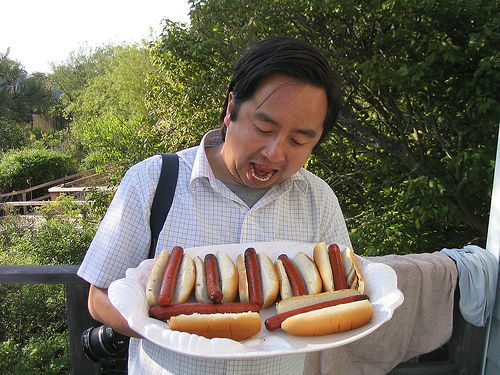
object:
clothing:
[441, 244, 500, 328]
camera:
[76, 325, 132, 363]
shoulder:
[141, 144, 202, 208]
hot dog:
[148, 301, 261, 319]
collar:
[188, 126, 308, 204]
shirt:
[75, 126, 356, 375]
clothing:
[306, 250, 460, 375]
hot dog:
[264, 292, 372, 332]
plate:
[106, 240, 405, 360]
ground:
[335, 130, 376, 183]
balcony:
[0, 137, 499, 372]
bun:
[146, 248, 195, 307]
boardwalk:
[2, 160, 129, 222]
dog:
[244, 247, 263, 307]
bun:
[166, 310, 262, 341]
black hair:
[218, 37, 342, 146]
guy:
[75, 38, 352, 373]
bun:
[276, 289, 373, 337]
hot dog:
[157, 246, 184, 305]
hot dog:
[203, 253, 223, 303]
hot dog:
[245, 246, 264, 307]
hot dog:
[278, 253, 307, 296]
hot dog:
[327, 244, 349, 291]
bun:
[194, 251, 240, 303]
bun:
[235, 252, 280, 308]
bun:
[275, 251, 323, 299]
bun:
[313, 241, 364, 294]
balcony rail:
[2, 251, 487, 373]